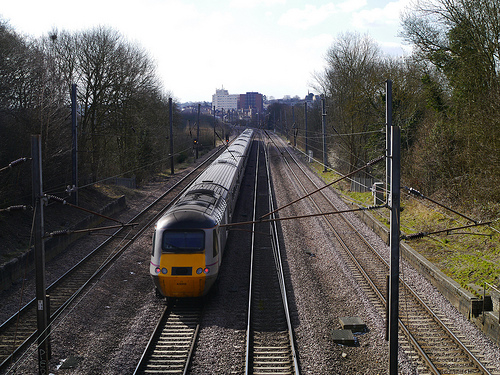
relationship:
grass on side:
[293, 131, 499, 312] [296, 133, 498, 299]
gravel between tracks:
[205, 297, 241, 370] [0, 124, 497, 372]